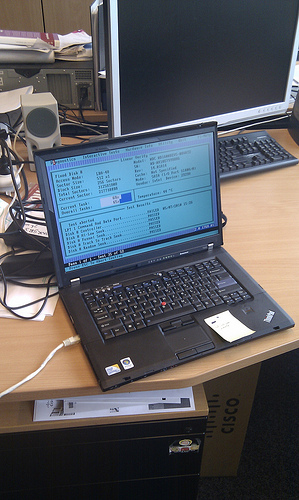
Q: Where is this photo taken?
A: In an office.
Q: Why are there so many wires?
A: For the computers.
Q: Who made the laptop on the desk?
A: Toshiba.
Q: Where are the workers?
A: At lunch.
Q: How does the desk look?
A: Cluttered.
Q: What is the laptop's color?
A: Black.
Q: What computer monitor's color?
A: Gray.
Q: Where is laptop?
A: Desk.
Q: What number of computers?
A: 2.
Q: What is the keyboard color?
A: Black.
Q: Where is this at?
A: Inside house.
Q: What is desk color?
A: Tan.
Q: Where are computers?
A: On a table.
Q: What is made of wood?
A: The table.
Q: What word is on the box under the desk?
A: Cisco.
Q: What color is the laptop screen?
A: Blue.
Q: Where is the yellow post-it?
A: On the laptop.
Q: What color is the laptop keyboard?
A: Black.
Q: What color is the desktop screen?
A: Black.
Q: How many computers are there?
A: 2.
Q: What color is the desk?
A: Brown.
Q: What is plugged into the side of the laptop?
A: Cord.